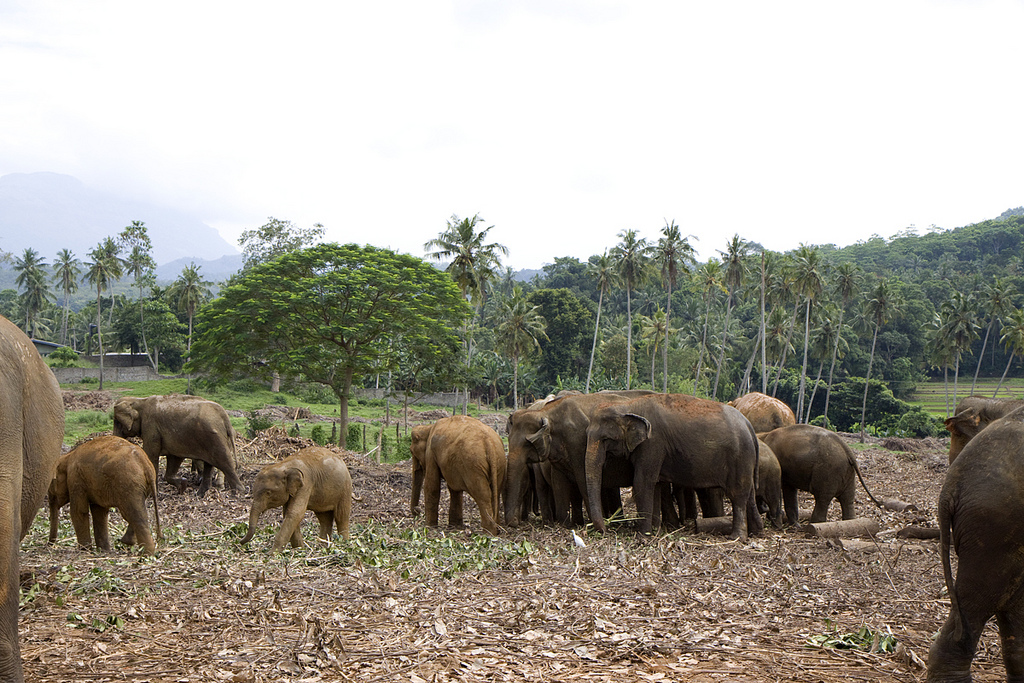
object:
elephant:
[410, 415, 508, 536]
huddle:
[411, 391, 882, 542]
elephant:
[586, 392, 766, 540]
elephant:
[506, 398, 591, 528]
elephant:
[506, 394, 630, 527]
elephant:
[758, 425, 884, 523]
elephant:
[758, 433, 783, 528]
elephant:
[47, 435, 160, 550]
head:
[47, 452, 69, 509]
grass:
[351, 518, 535, 580]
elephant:
[506, 390, 657, 536]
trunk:
[584, 440, 608, 531]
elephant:
[506, 390, 654, 532]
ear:
[625, 413, 652, 451]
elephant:
[241, 446, 350, 557]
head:
[252, 468, 306, 510]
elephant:
[504, 389, 759, 542]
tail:
[487, 437, 500, 520]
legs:
[266, 488, 312, 555]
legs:
[469, 490, 497, 535]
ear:
[287, 467, 304, 493]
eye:
[600, 418, 608, 424]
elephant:
[506, 390, 660, 528]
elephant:
[47, 435, 164, 552]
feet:
[71, 500, 159, 555]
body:
[140, 394, 241, 458]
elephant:
[113, 394, 245, 497]